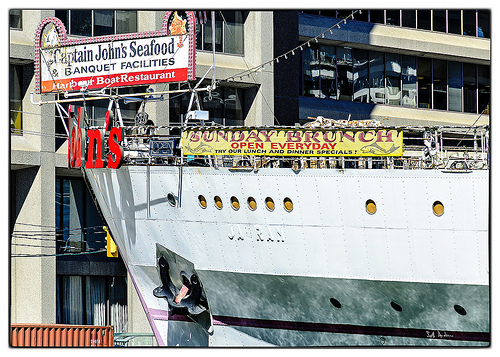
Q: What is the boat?
A: White.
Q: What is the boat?
A: White.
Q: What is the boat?
A: White.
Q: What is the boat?
A: White.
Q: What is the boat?
A: White.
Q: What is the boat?
A: White.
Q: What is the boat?
A: White.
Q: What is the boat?
A: White.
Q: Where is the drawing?
A: Side of boat.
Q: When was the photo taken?
A: Sunny day.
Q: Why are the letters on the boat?
A: Advertisement.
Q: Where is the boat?
A: In front of building.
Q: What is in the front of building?
A: Windows.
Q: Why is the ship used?
A: To sail in water.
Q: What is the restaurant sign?
A: White red and blue.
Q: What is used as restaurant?
A: Large ship.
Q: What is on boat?
A: Metal railing.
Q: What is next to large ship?
A: White building.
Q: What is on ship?
A: String of lights.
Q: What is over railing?
A: Yellow banner.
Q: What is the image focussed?
A: Front of ship.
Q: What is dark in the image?
A: Windows.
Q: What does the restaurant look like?
A: A boat.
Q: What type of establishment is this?
A: A restaurant.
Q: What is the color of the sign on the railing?
A: Yellow.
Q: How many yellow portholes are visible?
A: Eight.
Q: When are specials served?
A: Lunch and dinner.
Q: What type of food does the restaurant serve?
A: Seafood.